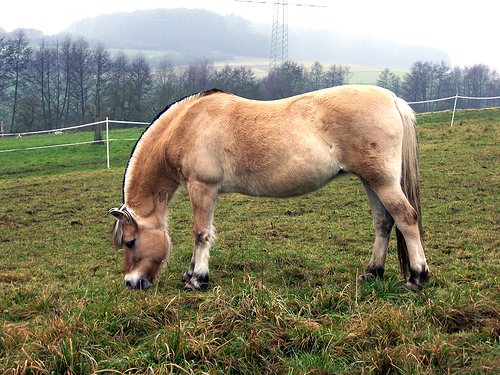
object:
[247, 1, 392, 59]
light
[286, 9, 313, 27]
sky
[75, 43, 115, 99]
haze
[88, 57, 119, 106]
tree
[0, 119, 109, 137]
line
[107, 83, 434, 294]
horse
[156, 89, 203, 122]
mane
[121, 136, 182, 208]
neck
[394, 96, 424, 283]
tail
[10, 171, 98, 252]
grass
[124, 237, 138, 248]
eye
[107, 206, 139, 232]
ear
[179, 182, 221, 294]
leg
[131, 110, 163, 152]
hair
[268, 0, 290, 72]
object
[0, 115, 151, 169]
fence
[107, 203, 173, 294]
head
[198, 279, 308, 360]
wisp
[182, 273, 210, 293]
hoof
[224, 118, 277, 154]
fur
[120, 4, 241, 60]
cloud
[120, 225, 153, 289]
face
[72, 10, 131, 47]
hill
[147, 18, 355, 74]
background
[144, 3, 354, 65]
fog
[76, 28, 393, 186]
distance